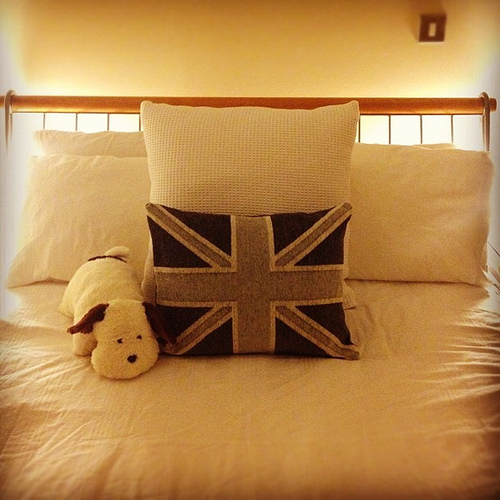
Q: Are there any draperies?
A: No, there are no draperies.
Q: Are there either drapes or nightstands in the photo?
A: No, there are no drapes or nightstands.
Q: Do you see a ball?
A: No, there are no balls.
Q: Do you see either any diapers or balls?
A: No, there are no balls or diapers.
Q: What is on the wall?
A: The light switch is on the wall.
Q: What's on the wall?
A: The light switch is on the wall.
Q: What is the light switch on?
A: The light switch is on the wall.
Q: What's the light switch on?
A: The light switch is on the wall.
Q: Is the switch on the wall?
A: Yes, the switch is on the wall.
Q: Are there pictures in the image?
A: No, there are no pictures.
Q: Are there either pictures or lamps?
A: No, there are no pictures or lamps.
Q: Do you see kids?
A: No, there are no kids.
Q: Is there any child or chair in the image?
A: No, there are no children or chairs.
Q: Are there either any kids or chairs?
A: No, there are no kids or chairs.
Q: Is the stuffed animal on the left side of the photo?
A: Yes, the stuffed animal is on the left of the image.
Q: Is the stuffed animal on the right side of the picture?
A: No, the stuffed animal is on the left of the image.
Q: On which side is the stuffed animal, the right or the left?
A: The stuffed animal is on the left of the image.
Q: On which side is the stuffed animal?
A: The stuffed animal is on the left of the image.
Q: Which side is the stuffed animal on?
A: The stuffed animal is on the left of the image.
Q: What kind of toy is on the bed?
A: The toy is a stuffed animal.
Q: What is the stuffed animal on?
A: The stuffed animal is on the bed.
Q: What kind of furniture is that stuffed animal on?
A: The stuffed animal is on the bed.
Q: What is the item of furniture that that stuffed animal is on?
A: The piece of furniture is a bed.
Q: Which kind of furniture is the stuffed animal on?
A: The stuffed animal is on the bed.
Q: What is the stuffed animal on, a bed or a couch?
A: The stuffed animal is on a bed.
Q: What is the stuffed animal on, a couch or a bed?
A: The stuffed animal is on a bed.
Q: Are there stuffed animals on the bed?
A: Yes, there is a stuffed animal on the bed.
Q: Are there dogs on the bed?
A: No, there is a stuffed animal on the bed.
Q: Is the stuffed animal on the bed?
A: Yes, the stuffed animal is on the bed.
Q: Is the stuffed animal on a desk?
A: No, the stuffed animal is on the bed.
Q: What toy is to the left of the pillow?
A: The toy is a stuffed animal.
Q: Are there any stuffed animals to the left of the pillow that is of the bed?
A: Yes, there is a stuffed animal to the left of the pillow.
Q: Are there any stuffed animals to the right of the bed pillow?
A: No, the stuffed animal is to the left of the pillow.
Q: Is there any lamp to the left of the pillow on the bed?
A: No, there is a stuffed animal to the left of the pillow.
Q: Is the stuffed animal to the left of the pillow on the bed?
A: Yes, the stuffed animal is to the left of the pillow.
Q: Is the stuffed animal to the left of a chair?
A: No, the stuffed animal is to the left of the pillow.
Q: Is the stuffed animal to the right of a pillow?
A: No, the stuffed animal is to the left of a pillow.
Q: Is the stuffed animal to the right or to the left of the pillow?
A: The stuffed animal is to the left of the pillow.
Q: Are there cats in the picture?
A: No, there are no cats.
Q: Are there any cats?
A: No, there are no cats.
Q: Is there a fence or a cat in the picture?
A: No, there are no cats or fences.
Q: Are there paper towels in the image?
A: No, there are no paper towels.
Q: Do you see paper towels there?
A: No, there are no paper towels.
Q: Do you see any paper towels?
A: No, there are no paper towels.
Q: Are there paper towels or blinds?
A: No, there are no paper towels or blinds.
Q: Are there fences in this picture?
A: No, there are no fences.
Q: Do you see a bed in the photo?
A: Yes, there is a bed.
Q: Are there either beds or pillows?
A: Yes, there is a bed.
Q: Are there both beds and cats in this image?
A: No, there is a bed but no cats.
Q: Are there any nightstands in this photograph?
A: No, there are no nightstands.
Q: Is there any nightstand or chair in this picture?
A: No, there are no nightstands or chairs.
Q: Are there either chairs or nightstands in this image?
A: No, there are no nightstands or chairs.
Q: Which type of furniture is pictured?
A: The furniture is a bed.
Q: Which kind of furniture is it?
A: The piece of furniture is a bed.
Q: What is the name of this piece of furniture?
A: That is a bed.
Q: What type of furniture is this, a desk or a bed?
A: That is a bed.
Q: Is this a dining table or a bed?
A: This is a bed.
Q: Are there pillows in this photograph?
A: Yes, there is a pillow.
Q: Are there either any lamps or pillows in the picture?
A: Yes, there is a pillow.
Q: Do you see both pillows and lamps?
A: No, there is a pillow but no lamps.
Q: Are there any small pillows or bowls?
A: Yes, there is a small pillow.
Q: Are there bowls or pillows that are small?
A: Yes, the pillow is small.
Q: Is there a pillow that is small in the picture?
A: Yes, there is a small pillow.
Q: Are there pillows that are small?
A: Yes, there is a pillow that is small.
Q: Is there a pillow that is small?
A: Yes, there is a pillow that is small.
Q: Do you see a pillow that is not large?
A: Yes, there is a small pillow.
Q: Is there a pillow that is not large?
A: Yes, there is a small pillow.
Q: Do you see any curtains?
A: No, there are no curtains.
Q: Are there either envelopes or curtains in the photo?
A: No, there are no curtains or envelopes.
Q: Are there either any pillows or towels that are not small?
A: No, there is a pillow but it is small.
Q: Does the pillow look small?
A: Yes, the pillow is small.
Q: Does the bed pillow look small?
A: Yes, the pillow is small.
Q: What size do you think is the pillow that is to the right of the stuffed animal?
A: The pillow is small.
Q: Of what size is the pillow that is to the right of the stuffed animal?
A: The pillow is small.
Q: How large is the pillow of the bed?
A: The pillow is small.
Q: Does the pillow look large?
A: No, the pillow is small.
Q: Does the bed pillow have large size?
A: No, the pillow is small.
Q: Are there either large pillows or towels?
A: No, there is a pillow but it is small.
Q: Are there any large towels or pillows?
A: No, there is a pillow but it is small.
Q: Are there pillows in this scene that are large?
A: No, there is a pillow but it is small.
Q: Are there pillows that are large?
A: No, there is a pillow but it is small.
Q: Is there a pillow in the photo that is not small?
A: No, there is a pillow but it is small.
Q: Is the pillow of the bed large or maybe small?
A: The pillow is small.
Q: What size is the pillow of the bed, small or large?
A: The pillow is small.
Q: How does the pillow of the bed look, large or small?
A: The pillow is small.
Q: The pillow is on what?
A: The pillow is on the bed.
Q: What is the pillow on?
A: The pillow is on the bed.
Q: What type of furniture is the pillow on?
A: The pillow is on the bed.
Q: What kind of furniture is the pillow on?
A: The pillow is on the bed.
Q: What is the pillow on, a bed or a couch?
A: The pillow is on a bed.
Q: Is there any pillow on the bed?
A: Yes, there is a pillow on the bed.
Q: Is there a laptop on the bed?
A: No, there is a pillow on the bed.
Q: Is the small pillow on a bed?
A: Yes, the pillow is on a bed.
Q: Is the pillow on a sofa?
A: No, the pillow is on a bed.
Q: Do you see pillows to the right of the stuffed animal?
A: Yes, there is a pillow to the right of the stuffed animal.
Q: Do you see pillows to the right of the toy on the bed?
A: Yes, there is a pillow to the right of the stuffed animal.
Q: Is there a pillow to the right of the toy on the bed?
A: Yes, there is a pillow to the right of the stuffed animal.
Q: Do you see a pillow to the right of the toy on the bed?
A: Yes, there is a pillow to the right of the stuffed animal.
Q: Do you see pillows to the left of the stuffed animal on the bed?
A: No, the pillow is to the right of the stuffed animal.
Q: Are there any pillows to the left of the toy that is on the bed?
A: No, the pillow is to the right of the stuffed animal.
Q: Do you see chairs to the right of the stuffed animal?
A: No, there is a pillow to the right of the stuffed animal.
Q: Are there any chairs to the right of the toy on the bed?
A: No, there is a pillow to the right of the stuffed animal.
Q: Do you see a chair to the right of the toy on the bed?
A: No, there is a pillow to the right of the stuffed animal.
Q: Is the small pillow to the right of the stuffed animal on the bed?
A: Yes, the pillow is to the right of the stuffed animal.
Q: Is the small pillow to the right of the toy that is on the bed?
A: Yes, the pillow is to the right of the stuffed animal.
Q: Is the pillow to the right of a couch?
A: No, the pillow is to the right of the stuffed animal.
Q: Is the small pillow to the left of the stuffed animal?
A: No, the pillow is to the right of the stuffed animal.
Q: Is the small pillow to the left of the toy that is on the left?
A: No, the pillow is to the right of the stuffed animal.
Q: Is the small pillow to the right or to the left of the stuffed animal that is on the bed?
A: The pillow is to the right of the stuffed animal.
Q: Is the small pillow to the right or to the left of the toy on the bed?
A: The pillow is to the right of the stuffed animal.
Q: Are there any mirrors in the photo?
A: No, there are no mirrors.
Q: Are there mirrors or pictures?
A: No, there are no mirrors or pictures.